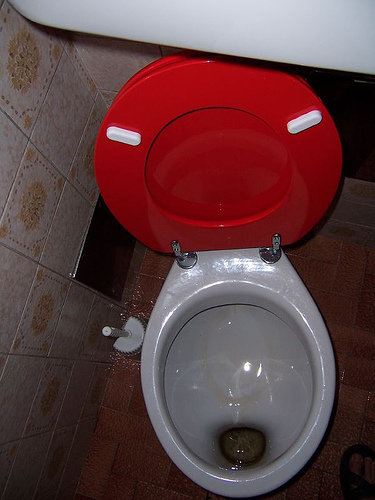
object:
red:
[161, 107, 267, 198]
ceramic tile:
[38, 181, 94, 279]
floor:
[335, 200, 372, 252]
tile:
[30, 42, 98, 176]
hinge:
[170, 244, 199, 269]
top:
[13, 0, 374, 74]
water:
[222, 425, 256, 451]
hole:
[216, 424, 266, 467]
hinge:
[259, 234, 283, 264]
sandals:
[338, 444, 375, 497]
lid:
[91, 47, 342, 249]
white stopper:
[104, 125, 144, 148]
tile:
[55, 424, 98, 500]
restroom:
[0, 0, 372, 496]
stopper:
[287, 110, 323, 135]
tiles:
[74, 235, 374, 498]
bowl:
[137, 248, 335, 498]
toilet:
[92, 47, 345, 500]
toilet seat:
[92, 53, 343, 262]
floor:
[323, 273, 346, 333]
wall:
[0, 4, 118, 500]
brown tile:
[3, 146, 66, 259]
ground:
[63, 172, 373, 497]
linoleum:
[77, 240, 375, 498]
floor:
[339, 440, 373, 500]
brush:
[101, 315, 147, 357]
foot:
[341, 445, 373, 497]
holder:
[111, 316, 143, 355]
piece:
[283, 106, 322, 131]